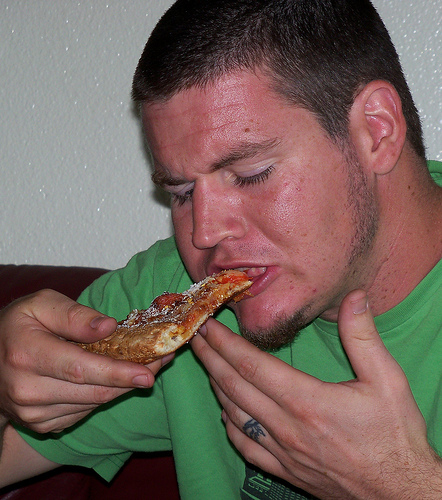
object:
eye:
[168, 183, 193, 205]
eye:
[224, 159, 279, 186]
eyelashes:
[172, 189, 193, 207]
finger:
[195, 315, 297, 410]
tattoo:
[242, 417, 266, 443]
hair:
[128, 0, 426, 162]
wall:
[1, 1, 439, 278]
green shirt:
[10, 161, 442, 500]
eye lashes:
[230, 165, 277, 188]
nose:
[189, 179, 247, 249]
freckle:
[411, 192, 415, 196]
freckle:
[407, 185, 410, 189]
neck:
[325, 173, 442, 320]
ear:
[346, 79, 407, 175]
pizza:
[67, 266, 252, 362]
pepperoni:
[151, 291, 186, 308]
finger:
[205, 379, 279, 457]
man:
[3, 1, 440, 500]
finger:
[188, 332, 282, 439]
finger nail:
[192, 322, 208, 338]